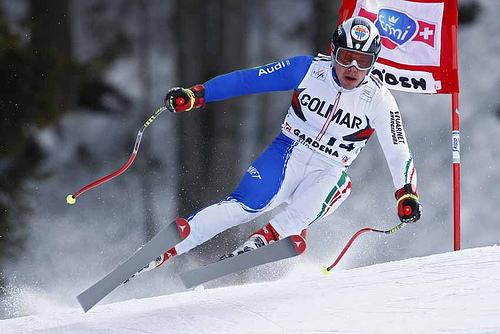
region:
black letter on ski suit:
[303, 97, 319, 112]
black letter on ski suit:
[315, 98, 327, 120]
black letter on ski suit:
[323, 101, 343, 129]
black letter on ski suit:
[338, 110, 350, 127]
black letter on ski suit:
[349, 109, 362, 129]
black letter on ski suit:
[292, 123, 300, 142]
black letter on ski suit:
[298, 127, 306, 143]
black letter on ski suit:
[303, 131, 313, 148]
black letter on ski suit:
[311, 138, 321, 150]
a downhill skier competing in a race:
[58, 1, 433, 318]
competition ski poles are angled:
[60, 82, 199, 208]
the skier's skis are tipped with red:
[73, 215, 191, 316]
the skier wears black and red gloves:
[391, 178, 424, 230]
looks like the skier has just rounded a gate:
[59, 0, 471, 325]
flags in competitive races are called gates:
[325, 0, 467, 252]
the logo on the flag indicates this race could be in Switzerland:
[326, 0, 465, 251]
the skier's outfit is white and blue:
[118, 50, 428, 281]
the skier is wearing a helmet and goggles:
[325, 13, 386, 93]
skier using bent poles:
[47, 27, 459, 332]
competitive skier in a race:
[51, 7, 476, 302]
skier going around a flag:
[49, 12, 471, 329]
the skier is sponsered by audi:
[45, 20, 437, 318]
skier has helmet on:
[311, 16, 447, 146]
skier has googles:
[311, 1, 450, 156]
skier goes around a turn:
[14, 12, 456, 332]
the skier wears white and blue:
[33, 14, 497, 264]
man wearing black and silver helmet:
[331, 12, 381, 92]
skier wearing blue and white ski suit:
[71, 16, 423, 309]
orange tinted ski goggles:
[333, 43, 378, 73]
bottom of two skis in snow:
[74, 218, 304, 317]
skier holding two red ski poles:
[48, 16, 421, 321]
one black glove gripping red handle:
[165, 84, 195, 111]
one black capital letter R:
[352, 112, 362, 133]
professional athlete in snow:
[71, 16, 427, 315]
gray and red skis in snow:
[76, 213, 307, 315]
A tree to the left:
[4, 34, 89, 170]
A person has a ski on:
[72, 217, 192, 310]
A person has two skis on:
[73, 206, 313, 323]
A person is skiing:
[57, 22, 437, 322]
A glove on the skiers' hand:
[393, 182, 426, 233]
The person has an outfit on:
[152, 13, 437, 306]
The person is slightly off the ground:
[69, 25, 445, 310]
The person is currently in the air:
[43, 27, 426, 327]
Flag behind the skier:
[340, 0, 477, 125]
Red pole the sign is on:
[448, 80, 463, 244]